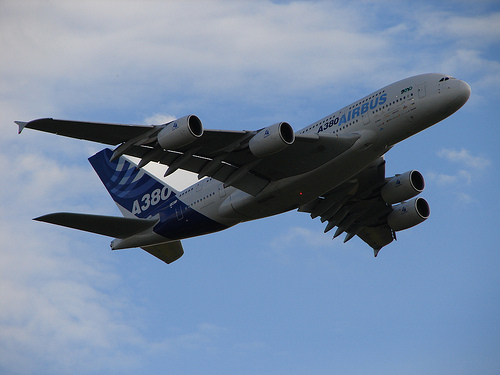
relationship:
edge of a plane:
[31, 149, 206, 269] [23, 56, 473, 280]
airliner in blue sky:
[17, 69, 469, 273] [1, 0, 497, 372]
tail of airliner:
[30, 195, 210, 299] [12, 71, 472, 266]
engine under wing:
[136, 110, 313, 177] [22, 102, 313, 215]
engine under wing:
[378, 166, 461, 226] [8, 110, 358, 191]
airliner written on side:
[12, 71, 472, 266] [108, 66, 447, 229]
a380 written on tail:
[130, 184, 171, 217] [29, 147, 184, 265]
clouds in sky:
[178, 23, 343, 74] [0, 13, 413, 95]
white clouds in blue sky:
[21, 19, 146, 85] [1, 0, 497, 372]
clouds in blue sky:
[1, 12, 400, 66] [1, 0, 497, 372]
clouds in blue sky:
[145, 22, 340, 89] [1, 0, 497, 372]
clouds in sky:
[139, 36, 259, 76] [331, 289, 448, 345]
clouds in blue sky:
[439, 146, 486, 181] [1, 0, 497, 372]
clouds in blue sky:
[12, 12, 34, 81] [1, 0, 497, 372]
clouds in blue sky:
[23, 294, 121, 345] [1, 0, 497, 372]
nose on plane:
[436, 74, 471, 104] [11, 67, 478, 267]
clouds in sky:
[120, 11, 238, 55] [245, 255, 432, 314]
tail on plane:
[30, 147, 187, 265] [9, 52, 481, 307]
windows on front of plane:
[433, 73, 454, 90] [11, 67, 478, 267]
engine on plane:
[241, 130, 308, 174] [62, 74, 476, 259]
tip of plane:
[433, 65, 476, 118] [23, 56, 473, 280]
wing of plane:
[11, 109, 366, 199] [11, 67, 478, 267]